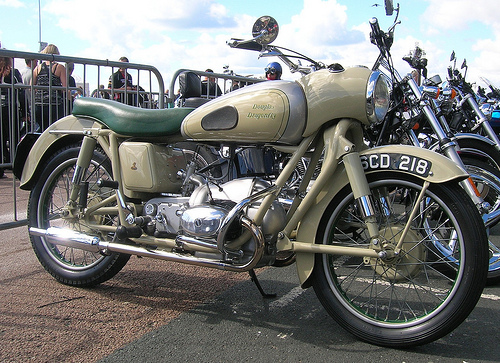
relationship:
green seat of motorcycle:
[71, 93, 201, 138] [13, 0, 490, 350]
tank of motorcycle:
[180, 79, 307, 146] [13, 0, 490, 350]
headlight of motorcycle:
[312, 53, 411, 160] [38, 42, 473, 331]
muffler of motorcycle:
[28, 212, 263, 275] [13, 0, 490, 350]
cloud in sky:
[43, 1, 207, 42] [1, 2, 498, 95]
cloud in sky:
[417, 1, 497, 34] [1, 2, 498, 95]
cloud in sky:
[457, 35, 498, 92] [1, 2, 498, 95]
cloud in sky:
[265, 1, 437, 88] [1, 2, 498, 95]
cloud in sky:
[85, 30, 237, 82] [1, 2, 498, 95]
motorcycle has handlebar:
[166, 3, 498, 289] [345, 7, 405, 62]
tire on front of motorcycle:
[306, 171, 489, 356] [32, 59, 499, 346]